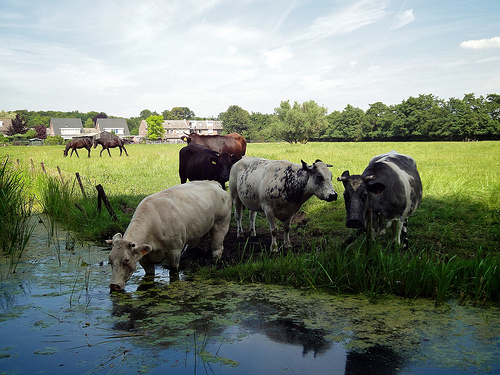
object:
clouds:
[128, 6, 278, 74]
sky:
[2, 2, 497, 89]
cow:
[104, 180, 232, 293]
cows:
[106, 180, 232, 290]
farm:
[2, 140, 499, 375]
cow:
[229, 157, 337, 258]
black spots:
[239, 182, 255, 201]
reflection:
[104, 279, 238, 348]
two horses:
[63, 138, 129, 158]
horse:
[63, 138, 93, 158]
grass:
[12, 156, 159, 194]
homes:
[47, 118, 84, 145]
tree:
[145, 115, 165, 144]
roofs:
[50, 118, 84, 136]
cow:
[181, 127, 246, 157]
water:
[10, 292, 499, 374]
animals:
[336, 151, 423, 260]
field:
[1, 144, 490, 300]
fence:
[3, 153, 118, 222]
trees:
[221, 105, 254, 140]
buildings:
[138, 119, 224, 144]